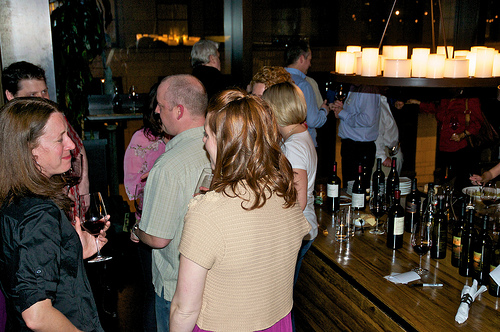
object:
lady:
[0, 95, 111, 332]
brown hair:
[0, 94, 87, 204]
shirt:
[0, 186, 104, 329]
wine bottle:
[385, 187, 406, 250]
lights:
[328, 43, 500, 89]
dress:
[183, 297, 302, 329]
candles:
[379, 57, 415, 80]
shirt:
[418, 98, 484, 153]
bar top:
[314, 195, 499, 330]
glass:
[77, 191, 115, 265]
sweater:
[175, 173, 315, 332]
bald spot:
[150, 75, 211, 106]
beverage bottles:
[321, 159, 342, 217]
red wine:
[80, 218, 107, 238]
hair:
[260, 81, 308, 130]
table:
[289, 180, 499, 330]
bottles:
[348, 162, 367, 209]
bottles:
[371, 157, 386, 204]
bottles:
[384, 156, 402, 199]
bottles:
[403, 176, 423, 235]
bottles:
[466, 213, 495, 287]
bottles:
[429, 195, 450, 260]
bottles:
[450, 200, 471, 266]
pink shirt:
[122, 125, 169, 202]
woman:
[172, 87, 312, 332]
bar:
[0, 1, 500, 332]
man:
[126, 71, 215, 328]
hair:
[188, 86, 310, 211]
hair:
[156, 73, 206, 119]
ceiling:
[0, 0, 499, 18]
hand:
[73, 214, 112, 260]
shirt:
[131, 122, 214, 307]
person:
[403, 86, 486, 185]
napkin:
[380, 267, 424, 287]